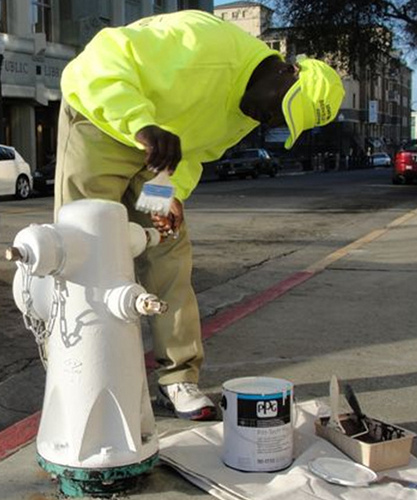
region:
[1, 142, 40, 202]
part of a white car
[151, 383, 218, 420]
a man's tennis shoe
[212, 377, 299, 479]
a can of paint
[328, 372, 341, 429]
part of a paint brush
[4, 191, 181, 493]
a tall white fire hydrant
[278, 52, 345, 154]
a green baseball cap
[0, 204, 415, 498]
part of a sidewalk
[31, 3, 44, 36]
the window of a building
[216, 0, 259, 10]
the roof of a building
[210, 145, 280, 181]
an old car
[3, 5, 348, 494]
Man is painting a fire hydrant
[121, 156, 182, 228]
Paintbrush with white paint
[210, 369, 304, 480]
A can of paint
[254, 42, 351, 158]
Yellow hat on man's head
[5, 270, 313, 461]
Curb is painted red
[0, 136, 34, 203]
A white parked car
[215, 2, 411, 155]
Brown buildings in the background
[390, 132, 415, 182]
A parked red car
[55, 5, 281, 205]
A bright yellow jacket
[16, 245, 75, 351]
Chain on a fire hydrant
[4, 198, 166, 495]
white fire hydrant on side of road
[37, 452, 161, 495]
non painted part of fire hydrant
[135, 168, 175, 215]
paint brush with with paint on it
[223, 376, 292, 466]
can of white paint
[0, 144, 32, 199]
part of white car parked on the street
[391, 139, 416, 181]
part of red car on the side of the road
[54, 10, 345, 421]
man painting the fire hydrant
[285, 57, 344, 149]
yellow and gray hat on man's head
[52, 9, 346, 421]
man wearing yellow sweater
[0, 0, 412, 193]
buildings on the left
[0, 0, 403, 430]
man is painting the hydrant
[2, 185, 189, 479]
the hydrant is white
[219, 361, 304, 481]
paint bucket next to man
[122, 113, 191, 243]
man holding a paint brush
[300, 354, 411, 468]
paint utensils on ground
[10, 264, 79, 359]
chain hanging on hydrant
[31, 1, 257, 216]
man's shirt is yellow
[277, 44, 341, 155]
man is wearing a hat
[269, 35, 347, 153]
the hat is yellow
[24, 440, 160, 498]
base of hydrant is green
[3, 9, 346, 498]
man painting a fire hydrant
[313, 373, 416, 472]
roller and paint brush in a pan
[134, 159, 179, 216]
paint brush in a man's hand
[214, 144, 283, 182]
car parked across the street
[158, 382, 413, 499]
white material on ground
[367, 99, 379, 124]
sign on the side of the street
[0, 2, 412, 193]
buildings on the street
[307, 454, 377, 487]
lid of the paint can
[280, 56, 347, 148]
a bright yellow cap